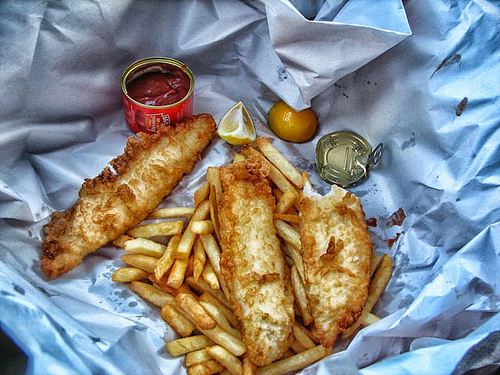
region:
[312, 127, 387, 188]
A silver lid of a can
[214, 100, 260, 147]
A slice of yellow lemon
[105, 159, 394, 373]
Many yellow french fries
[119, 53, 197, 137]
A small red can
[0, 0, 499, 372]
A blue crumpled fabric with food on it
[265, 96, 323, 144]
A round yellow lemon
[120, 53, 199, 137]
Red substance in a can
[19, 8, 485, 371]
an order of food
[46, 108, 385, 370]
three pieces of fish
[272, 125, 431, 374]
broken piece of fish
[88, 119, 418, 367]
fish on top of fries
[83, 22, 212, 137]
a can next to fish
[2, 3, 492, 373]
food on top of paper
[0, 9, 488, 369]
the paper is white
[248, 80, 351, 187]
a yellow lemon wedge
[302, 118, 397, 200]
lid to the can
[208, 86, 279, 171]
a slice of lemon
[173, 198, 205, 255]
french fry next to french fry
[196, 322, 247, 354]
french fry next to french fry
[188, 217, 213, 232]
french fry next to french fry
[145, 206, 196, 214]
french fry next to french fry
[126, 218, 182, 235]
french fry next to french fry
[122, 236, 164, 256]
french fry next to french fry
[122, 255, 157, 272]
french fry next to french fry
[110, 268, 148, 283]
french fry next to french fry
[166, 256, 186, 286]
french fry next to french fry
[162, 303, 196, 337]
french fry next to french fry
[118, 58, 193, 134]
A red opened can of tomato paste.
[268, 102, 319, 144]
Skin of an orange half.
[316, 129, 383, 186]
A gold can lid on a white paper.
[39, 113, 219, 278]
A large brown piece of fried fish touching a red can.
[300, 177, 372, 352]
Smallest piece of fish with bite taken out of it.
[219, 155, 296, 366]
Medium sized piece of fried fish over fries.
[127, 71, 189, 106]
Red paste in a red can.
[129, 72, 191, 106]
Thick red paste in a red can.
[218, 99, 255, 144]
An orange quarter touching a piece of fish.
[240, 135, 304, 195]
Two top most french fries.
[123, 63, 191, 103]
the food is red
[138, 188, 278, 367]
french fries on cloth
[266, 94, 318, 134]
the lemon is yellow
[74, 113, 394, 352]
the food is fried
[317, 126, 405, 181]
the top is silver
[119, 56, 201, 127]
the can is red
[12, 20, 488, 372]
the cloth is blue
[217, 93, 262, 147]
the lemon is cut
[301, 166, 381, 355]
the food is eaten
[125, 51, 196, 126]
the can is open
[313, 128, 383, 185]
aluminum top of a can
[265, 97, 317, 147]
whole yellow lemon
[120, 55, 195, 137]
opened aluminum can